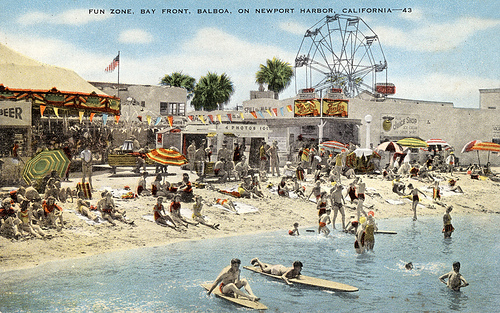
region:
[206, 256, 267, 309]
a man sitting on the surfboard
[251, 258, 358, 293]
man laying on the surfboard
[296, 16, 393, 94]
tall ride on the beach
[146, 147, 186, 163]
striped umbrella is open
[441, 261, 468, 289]
the woman is standing in the water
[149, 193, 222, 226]
three women sitting on the beach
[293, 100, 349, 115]
business sign on the building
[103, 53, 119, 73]
American flag on the post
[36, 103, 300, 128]
string with flags on it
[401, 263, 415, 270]
person's head above water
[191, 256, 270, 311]
person on a surfboard in the water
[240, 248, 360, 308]
person on a surfboard in the water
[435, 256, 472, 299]
person standing in the water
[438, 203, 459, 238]
person standing in the water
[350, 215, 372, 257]
person standing in the water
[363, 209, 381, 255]
person standing in the water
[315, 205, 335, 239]
person standing in the water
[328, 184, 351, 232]
person standing in the water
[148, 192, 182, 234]
person sitting on the beach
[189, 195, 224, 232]
person sitting on the beach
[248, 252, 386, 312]
The boy is on the surfboard.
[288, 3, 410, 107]
A ferris wheel in the park.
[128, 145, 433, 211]
People on the sand.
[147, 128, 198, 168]
Umbrella on the sand.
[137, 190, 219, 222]
People sitting on the sand.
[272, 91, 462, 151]
A building behind the people.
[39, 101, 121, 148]
A merry-go-round in the park.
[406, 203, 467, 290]
People in the water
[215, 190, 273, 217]
A towel on the sand.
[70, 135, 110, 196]
A person standing by the caurosel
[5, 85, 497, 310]
The people are at the beach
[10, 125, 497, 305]
Some people are using umbrellas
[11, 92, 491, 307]
Some people are laying in the sand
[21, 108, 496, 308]
Some people are doing some swimming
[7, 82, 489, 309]
Some people are on surfboards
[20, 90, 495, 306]
Some people are in the water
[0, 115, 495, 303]
The people are enjoying the sunshine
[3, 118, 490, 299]
The people are enjoying their time off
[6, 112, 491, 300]
The people are having a great time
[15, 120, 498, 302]
The people are enjoying their day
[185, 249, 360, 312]
young men on surfboards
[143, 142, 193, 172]
red and yellow beach umbrella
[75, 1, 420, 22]
postcard type identification at top of picture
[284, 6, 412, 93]
ferris wheel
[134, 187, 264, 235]
people on beach with blankets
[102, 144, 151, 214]
wooden bench behind beach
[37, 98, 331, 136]
colored triangle banner between buildings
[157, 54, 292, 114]
palm trees in background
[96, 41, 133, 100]
american flag above building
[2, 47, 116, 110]
tan tent like roof